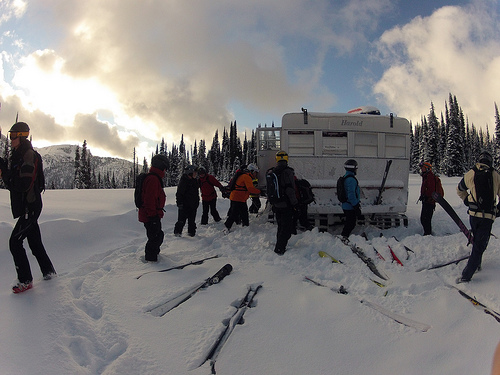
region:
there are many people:
[6, 142, 498, 261]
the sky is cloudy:
[79, 17, 255, 109]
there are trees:
[412, 117, 488, 164]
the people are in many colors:
[142, 157, 366, 224]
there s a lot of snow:
[16, 289, 166, 367]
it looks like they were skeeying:
[165, 262, 464, 323]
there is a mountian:
[44, 142, 128, 201]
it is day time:
[116, 13, 450, 105]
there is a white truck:
[280, 115, 435, 170]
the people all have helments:
[149, 132, 317, 187]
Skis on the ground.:
[139, 260, 265, 373]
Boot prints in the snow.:
[63, 273, 134, 370]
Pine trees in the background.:
[148, 124, 258, 181]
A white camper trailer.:
[280, 110, 411, 222]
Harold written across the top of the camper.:
[338, 115, 368, 127]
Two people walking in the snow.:
[172, 155, 227, 240]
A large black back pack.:
[466, 166, 495, 208]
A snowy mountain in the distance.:
[40, 138, 144, 191]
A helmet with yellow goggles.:
[8, 118, 35, 139]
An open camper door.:
[253, 125, 280, 188]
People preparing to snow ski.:
[126, 147, 371, 269]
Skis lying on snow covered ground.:
[127, 254, 282, 374]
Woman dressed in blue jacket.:
[336, 172, 365, 215]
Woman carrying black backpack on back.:
[333, 173, 351, 205]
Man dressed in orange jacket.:
[228, 168, 263, 203]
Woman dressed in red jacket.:
[132, 166, 168, 226]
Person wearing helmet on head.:
[8, 120, 33, 142]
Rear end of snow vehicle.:
[277, 110, 411, 228]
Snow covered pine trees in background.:
[418, 87, 495, 177]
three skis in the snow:
[150, 252, 279, 359]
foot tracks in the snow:
[54, 269, 121, 372]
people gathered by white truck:
[126, 156, 325, 261]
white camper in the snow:
[285, 107, 399, 230]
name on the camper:
[323, 108, 378, 137]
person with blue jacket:
[320, 152, 368, 245]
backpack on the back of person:
[125, 169, 151, 222]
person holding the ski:
[399, 142, 460, 244]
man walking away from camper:
[6, 110, 72, 312]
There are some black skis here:
[193, 318, 218, 369]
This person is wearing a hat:
[8, 120, 32, 146]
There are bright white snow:
[299, 322, 310, 348]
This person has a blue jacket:
[342, 184, 352, 207]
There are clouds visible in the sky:
[133, 59, 160, 137]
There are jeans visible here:
[467, 210, 492, 282]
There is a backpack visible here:
[265, 170, 288, 227]